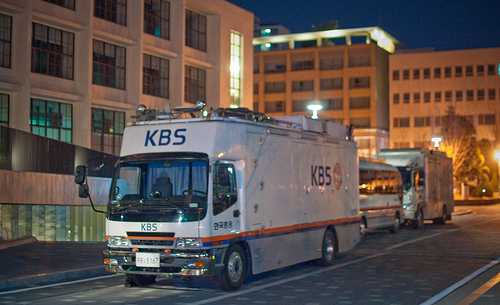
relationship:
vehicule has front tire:
[75, 104, 362, 292] [220, 246, 249, 289]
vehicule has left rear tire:
[75, 104, 362, 292] [321, 226, 340, 265]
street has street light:
[0, 202, 498, 304] [305, 102, 324, 118]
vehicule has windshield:
[75, 104, 362, 292] [110, 159, 209, 219]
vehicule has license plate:
[75, 104, 362, 292] [136, 251, 162, 270]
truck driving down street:
[376, 146, 455, 229] [0, 202, 498, 304]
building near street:
[2, 2, 255, 242] [0, 202, 498, 304]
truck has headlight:
[376, 146, 455, 229] [403, 204, 414, 212]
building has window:
[2, 2, 255, 242] [32, 22, 76, 82]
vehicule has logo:
[75, 104, 362, 292] [312, 165, 333, 184]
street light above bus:
[305, 102, 324, 118] [359, 160, 405, 232]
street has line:
[0, 202, 498, 304] [422, 254, 500, 303]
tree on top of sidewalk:
[430, 106, 485, 199] [456, 191, 499, 205]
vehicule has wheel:
[75, 104, 362, 292] [182, 189, 208, 198]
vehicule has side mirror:
[75, 104, 362, 292] [74, 165, 87, 184]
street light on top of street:
[305, 102, 324, 118] [0, 202, 498, 304]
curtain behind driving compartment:
[142, 163, 207, 195] [112, 156, 237, 219]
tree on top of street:
[430, 106, 485, 199] [0, 202, 498, 304]